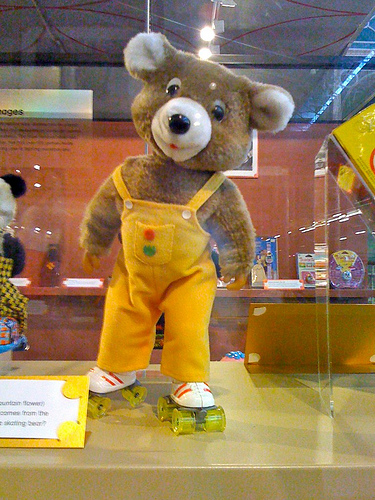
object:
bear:
[80, 30, 296, 409]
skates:
[88, 380, 148, 420]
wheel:
[172, 407, 196, 436]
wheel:
[202, 405, 226, 432]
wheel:
[122, 379, 148, 407]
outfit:
[98, 163, 226, 382]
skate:
[157, 395, 226, 436]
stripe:
[178, 388, 193, 398]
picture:
[224, 128, 258, 179]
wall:
[0, 121, 366, 281]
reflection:
[213, 53, 240, 64]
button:
[126, 200, 133, 208]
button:
[182, 210, 190, 219]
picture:
[251, 236, 278, 288]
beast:
[259, 249, 275, 273]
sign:
[62, 277, 104, 288]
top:
[21, 285, 108, 293]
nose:
[168, 114, 190, 134]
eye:
[166, 77, 182, 95]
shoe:
[87, 367, 137, 393]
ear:
[248, 82, 294, 130]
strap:
[112, 166, 131, 200]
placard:
[0, 374, 90, 448]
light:
[199, 26, 214, 42]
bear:
[0, 173, 26, 319]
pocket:
[134, 220, 175, 266]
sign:
[0, 88, 93, 121]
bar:
[1, 62, 124, 67]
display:
[0, 29, 373, 468]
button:
[144, 228, 154, 240]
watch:
[265, 237, 272, 279]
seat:
[0, 317, 28, 354]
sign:
[264, 279, 304, 290]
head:
[124, 33, 294, 171]